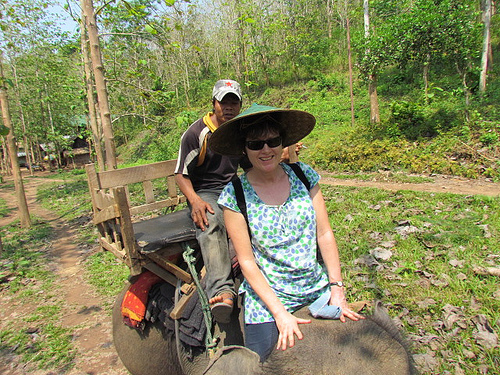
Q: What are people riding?
A: Elephant.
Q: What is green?
A: Grass.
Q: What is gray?
A: Elephant.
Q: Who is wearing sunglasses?
A: The woman.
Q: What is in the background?
A: Trees.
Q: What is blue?
A: Sky.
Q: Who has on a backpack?
A: The woman.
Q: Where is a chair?
A: On the elephant.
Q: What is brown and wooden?
A: Chair.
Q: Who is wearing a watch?
A: Woman riding elephant.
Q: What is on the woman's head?
A: A hat.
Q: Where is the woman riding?
A: On an elephant's back.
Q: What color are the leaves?
A: Green.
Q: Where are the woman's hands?
A: On the head of an elephant.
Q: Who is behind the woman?
A: A man.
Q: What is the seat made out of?
A: Wood.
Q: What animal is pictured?
A: An elephant.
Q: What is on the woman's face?
A: Sunglasses.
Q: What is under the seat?
A: Blankets.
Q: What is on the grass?
A: Tree bark.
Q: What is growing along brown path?
A: Grass.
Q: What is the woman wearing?
A: Wide brimmed hat.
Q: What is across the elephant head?
A: Hands.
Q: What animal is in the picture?
A: Elephant.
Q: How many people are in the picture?
A: Two.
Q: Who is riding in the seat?
A: The man.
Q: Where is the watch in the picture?
A: On the woman's wrist.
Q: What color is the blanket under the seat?
A: Orange.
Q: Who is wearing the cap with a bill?
A: The man.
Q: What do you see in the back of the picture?
A: Buildings.